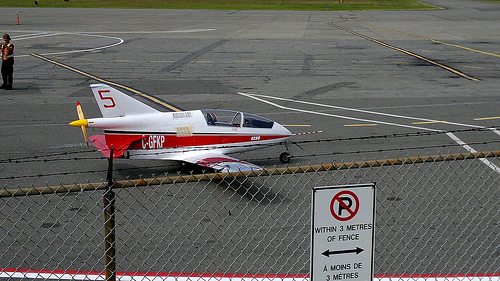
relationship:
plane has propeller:
[71, 80, 296, 182] [66, 99, 91, 146]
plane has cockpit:
[71, 80, 296, 182] [198, 105, 246, 131]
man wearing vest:
[0, 34, 16, 91] [0, 41, 18, 63]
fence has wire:
[0, 123, 499, 280] [1, 120, 500, 191]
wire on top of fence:
[1, 120, 500, 191] [0, 123, 499, 280]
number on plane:
[97, 88, 119, 113] [71, 80, 296, 182]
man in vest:
[0, 29, 20, 92] [0, 41, 18, 63]